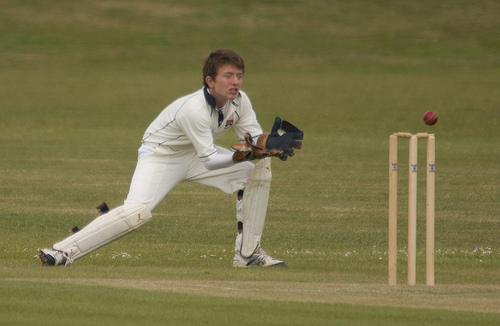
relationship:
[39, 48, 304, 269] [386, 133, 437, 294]
player playing cricket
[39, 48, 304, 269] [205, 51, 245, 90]
player has hair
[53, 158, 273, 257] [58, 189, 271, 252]
shin gaurds are worn on shins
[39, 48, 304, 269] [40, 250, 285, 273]
player has on cleats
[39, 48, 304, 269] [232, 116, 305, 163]
player has on gloves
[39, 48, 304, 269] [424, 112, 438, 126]
player catching ball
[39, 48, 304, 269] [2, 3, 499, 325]
player on field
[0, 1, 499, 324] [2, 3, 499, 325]
grass on field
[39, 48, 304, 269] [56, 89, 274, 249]
player in uniform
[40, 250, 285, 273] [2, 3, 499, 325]
sneakers on top of field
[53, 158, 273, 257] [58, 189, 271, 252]
gaurds are on shins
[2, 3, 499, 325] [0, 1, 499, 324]
field covered with grass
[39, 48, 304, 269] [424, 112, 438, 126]
player catches ball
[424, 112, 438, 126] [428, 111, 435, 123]
cricket ball has white stripe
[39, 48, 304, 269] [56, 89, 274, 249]
player wearing uniform